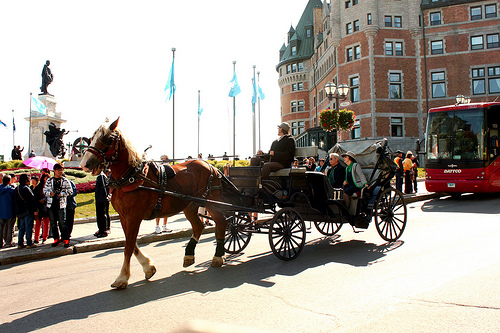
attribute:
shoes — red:
[48, 238, 68, 246]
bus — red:
[428, 89, 495, 225]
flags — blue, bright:
[162, 34, 270, 135]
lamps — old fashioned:
[340, 110, 353, 126]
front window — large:
[424, 104, 499, 170]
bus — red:
[416, 95, 498, 199]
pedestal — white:
[26, 92, 65, 164]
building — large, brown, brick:
[270, 7, 498, 234]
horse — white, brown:
[76, 112, 239, 291]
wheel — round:
[267, 203, 319, 267]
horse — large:
[57, 105, 269, 288]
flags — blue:
[144, 46, 199, 122]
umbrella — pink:
[23, 151, 58, 169]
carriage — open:
[209, 123, 414, 261]